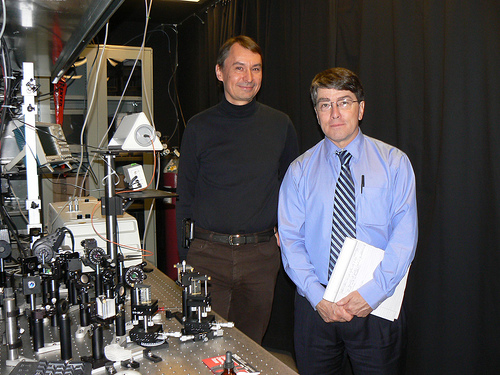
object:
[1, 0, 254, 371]
equipment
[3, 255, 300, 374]
workbench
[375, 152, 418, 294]
arm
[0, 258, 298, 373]
metal table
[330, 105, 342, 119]
nose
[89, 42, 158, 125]
white cabinet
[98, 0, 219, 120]
wall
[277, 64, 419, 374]
man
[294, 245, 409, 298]
waist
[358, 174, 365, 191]
pen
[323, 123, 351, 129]
mouth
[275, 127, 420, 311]
shirt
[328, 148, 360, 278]
striped tie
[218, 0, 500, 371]
curtain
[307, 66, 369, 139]
head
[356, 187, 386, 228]
pocket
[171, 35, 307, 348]
man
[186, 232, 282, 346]
brown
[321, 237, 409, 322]
papers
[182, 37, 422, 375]
scientists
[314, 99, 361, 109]
glasses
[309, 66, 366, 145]
face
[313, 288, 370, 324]
hands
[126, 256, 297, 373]
table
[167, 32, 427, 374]
guys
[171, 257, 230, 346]
microscope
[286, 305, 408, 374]
pants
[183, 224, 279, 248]
belt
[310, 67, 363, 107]
hair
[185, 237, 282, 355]
brown pants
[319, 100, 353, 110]
oldman eyes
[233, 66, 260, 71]
oldman eyes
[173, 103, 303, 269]
shirt